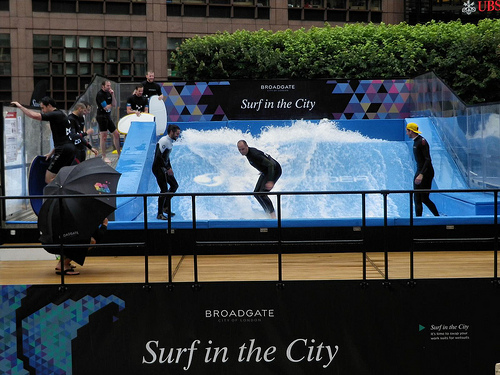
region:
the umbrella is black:
[38, 155, 123, 252]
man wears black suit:
[397, 117, 442, 218]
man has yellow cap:
[396, 115, 436, 166]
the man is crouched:
[233, 137, 288, 220]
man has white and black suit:
[145, 118, 190, 218]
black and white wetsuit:
[146, 135, 180, 212]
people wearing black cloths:
[14, 55, 164, 153]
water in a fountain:
[155, 109, 422, 216]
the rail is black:
[3, 180, 495, 282]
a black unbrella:
[58, 165, 129, 245]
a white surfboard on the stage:
[143, 90, 173, 135]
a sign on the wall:
[5, 111, 31, 161]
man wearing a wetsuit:
[240, 131, 276, 197]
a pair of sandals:
[53, 259, 85, 283]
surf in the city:
[145, 334, 345, 369]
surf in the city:
[233, 94, 320, 117]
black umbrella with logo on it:
[31, 160, 123, 230]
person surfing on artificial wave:
[231, 135, 283, 215]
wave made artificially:
[168, 126, 415, 222]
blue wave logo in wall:
[0, 286, 124, 373]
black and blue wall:
[3, 286, 494, 373]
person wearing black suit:
[405, 123, 450, 220]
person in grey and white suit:
[151, 120, 174, 215]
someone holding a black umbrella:
[37, 155, 122, 276]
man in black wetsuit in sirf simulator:
[235, 139, 284, 214]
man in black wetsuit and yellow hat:
[405, 122, 441, 218]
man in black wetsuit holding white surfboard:
[139, 70, 167, 138]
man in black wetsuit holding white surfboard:
[116, 85, 154, 132]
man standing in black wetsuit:
[94, 80, 122, 156]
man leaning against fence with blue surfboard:
[11, 96, 74, 216]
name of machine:
[238, 96, 318, 112]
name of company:
[260, 83, 298, 93]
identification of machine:
[140, 304, 342, 372]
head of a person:
[167, 113, 192, 138]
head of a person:
[235, 132, 257, 156]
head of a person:
[405, 113, 422, 137]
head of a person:
[39, 93, 57, 110]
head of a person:
[95, 76, 123, 100]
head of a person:
[143, 65, 160, 80]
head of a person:
[127, 81, 145, 99]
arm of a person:
[152, 138, 183, 190]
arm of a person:
[250, 143, 287, 195]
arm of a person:
[406, 148, 437, 190]